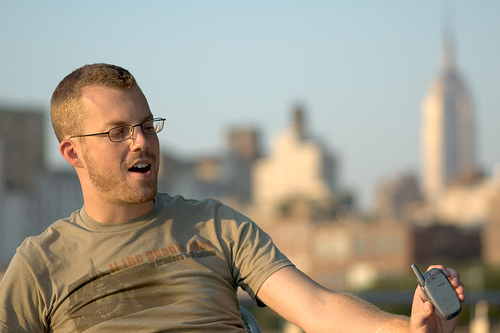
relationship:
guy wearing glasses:
[0, 63, 468, 332] [69, 116, 166, 143]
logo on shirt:
[66, 232, 224, 327] [0, 194, 292, 332]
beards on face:
[80, 147, 161, 203] [78, 80, 160, 203]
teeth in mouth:
[138, 161, 148, 169] [125, 159, 153, 175]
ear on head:
[58, 138, 83, 171] [47, 60, 159, 204]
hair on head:
[47, 59, 139, 141] [47, 60, 159, 204]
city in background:
[0, 1, 499, 289] [2, 0, 498, 330]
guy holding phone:
[0, 63, 468, 332] [395, 253, 495, 324]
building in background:
[419, 0, 483, 197] [2, 0, 498, 330]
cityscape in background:
[191, 114, 497, 292] [2, 0, 498, 330]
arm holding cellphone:
[223, 207, 463, 329] [407, 262, 462, 319]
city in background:
[0, 1, 499, 333] [2, 0, 498, 330]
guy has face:
[0, 63, 468, 332] [78, 80, 160, 203]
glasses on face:
[57, 112, 172, 144] [78, 80, 160, 203]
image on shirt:
[68, 237, 200, 328] [0, 194, 294, 332]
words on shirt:
[105, 238, 212, 272] [87, 231, 219, 301]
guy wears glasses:
[9, 52, 479, 332] [55, 110, 172, 147]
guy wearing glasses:
[0, 63, 468, 332] [63, 111, 185, 143]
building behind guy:
[419, 0, 483, 197] [0, 63, 468, 332]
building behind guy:
[249, 98, 356, 221] [0, 63, 468, 332]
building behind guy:
[184, 123, 261, 203] [0, 63, 468, 332]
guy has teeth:
[0, 63, 468, 332] [135, 160, 152, 170]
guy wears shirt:
[0, 63, 468, 332] [0, 194, 294, 332]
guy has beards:
[0, 63, 468, 332] [116, 152, 163, 203]